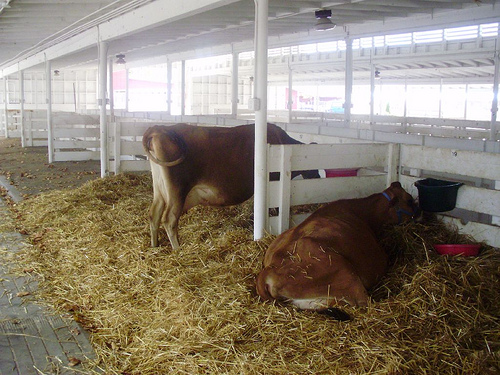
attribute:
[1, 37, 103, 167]
stalls — three, empty, white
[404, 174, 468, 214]
container — black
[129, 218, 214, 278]
feet — light brown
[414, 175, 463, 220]
bucket — black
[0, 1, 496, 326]
stalls — wooden, white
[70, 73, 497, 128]
windows — sunny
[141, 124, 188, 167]
tail — curled, brown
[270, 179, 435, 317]
cow — brown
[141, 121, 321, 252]
cow — brown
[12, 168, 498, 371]
straw — golden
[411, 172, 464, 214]
dish — black, plastic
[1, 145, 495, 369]
ground — concrete